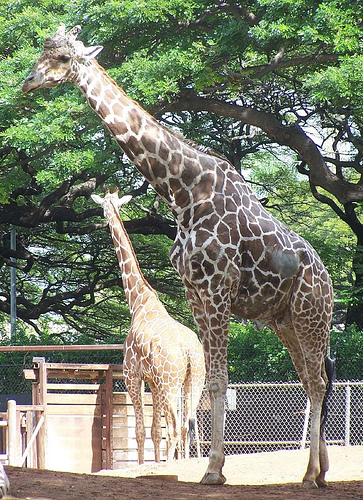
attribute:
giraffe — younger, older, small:
[22, 23, 331, 490]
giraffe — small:
[87, 185, 205, 465]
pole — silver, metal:
[7, 223, 18, 345]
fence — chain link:
[1, 362, 361, 457]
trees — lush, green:
[0, 9, 356, 169]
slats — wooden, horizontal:
[22, 356, 177, 473]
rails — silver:
[340, 370, 355, 475]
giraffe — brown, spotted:
[68, 121, 234, 393]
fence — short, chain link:
[234, 366, 299, 406]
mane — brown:
[108, 197, 159, 293]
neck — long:
[107, 212, 151, 307]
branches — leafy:
[242, 57, 316, 97]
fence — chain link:
[230, 364, 299, 454]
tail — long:
[178, 349, 200, 449]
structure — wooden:
[10, 350, 192, 463]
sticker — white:
[198, 388, 236, 410]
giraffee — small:
[80, 191, 231, 464]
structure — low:
[2, 339, 173, 465]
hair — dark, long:
[322, 354, 335, 425]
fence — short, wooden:
[12, 350, 198, 476]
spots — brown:
[189, 271, 229, 356]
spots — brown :
[214, 168, 243, 276]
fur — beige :
[152, 137, 210, 222]